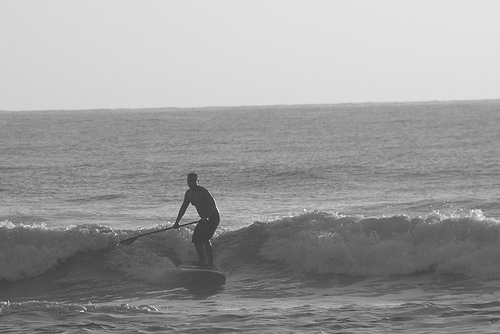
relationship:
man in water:
[148, 179, 245, 263] [302, 165, 443, 267]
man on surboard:
[148, 179, 245, 263] [184, 257, 222, 285]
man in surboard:
[148, 179, 245, 263] [184, 257, 222, 285]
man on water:
[148, 179, 245, 263] [302, 165, 443, 267]